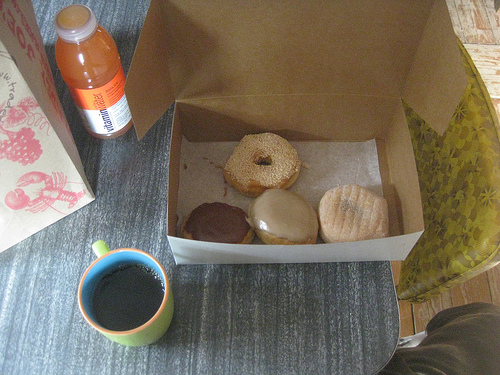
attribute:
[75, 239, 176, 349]
cup — blue, green, aqua blue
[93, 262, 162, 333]
coffee — black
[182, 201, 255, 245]
doughnut — brown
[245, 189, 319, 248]
donut — vanilla, frosted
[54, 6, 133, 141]
bottle — filled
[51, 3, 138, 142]
drink — orange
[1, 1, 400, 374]
table — grey, gray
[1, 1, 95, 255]
bag — paper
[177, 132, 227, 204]
paper — white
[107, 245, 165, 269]
rim — white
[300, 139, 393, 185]
tissue paper — white